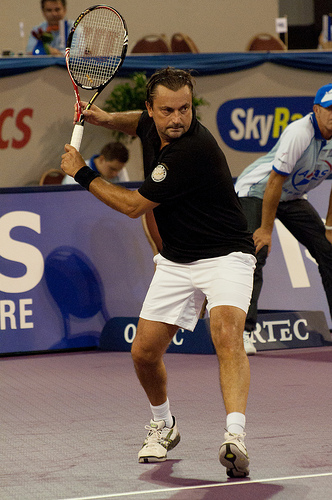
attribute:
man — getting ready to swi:
[59, 64, 275, 479]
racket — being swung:
[63, 3, 132, 150]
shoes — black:
[135, 414, 251, 484]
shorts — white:
[138, 250, 261, 331]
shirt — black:
[130, 107, 259, 256]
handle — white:
[71, 120, 89, 156]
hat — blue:
[313, 84, 331, 107]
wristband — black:
[72, 164, 105, 193]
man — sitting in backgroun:
[24, 0, 86, 59]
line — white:
[51, 469, 330, 500]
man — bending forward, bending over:
[236, 79, 328, 356]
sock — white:
[221, 406, 245, 437]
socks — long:
[140, 388, 247, 438]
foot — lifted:
[220, 427, 251, 485]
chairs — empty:
[131, 26, 287, 58]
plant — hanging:
[106, 71, 212, 142]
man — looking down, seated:
[64, 140, 134, 188]